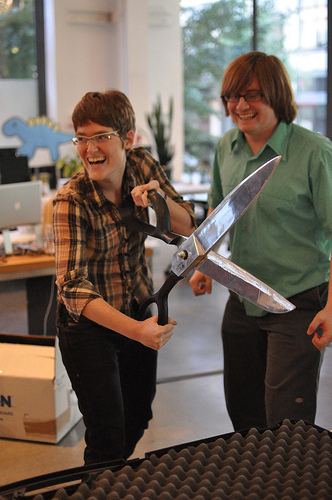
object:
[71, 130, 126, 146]
spectacles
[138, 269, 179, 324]
handle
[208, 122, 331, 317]
man shirt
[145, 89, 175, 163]
plant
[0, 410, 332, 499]
table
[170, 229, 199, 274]
dinosaur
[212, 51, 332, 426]
woman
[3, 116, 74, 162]
artwork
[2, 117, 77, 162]
dinosaur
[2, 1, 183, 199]
wall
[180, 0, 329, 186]
window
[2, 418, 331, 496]
case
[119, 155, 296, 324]
scissors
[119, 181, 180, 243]
handle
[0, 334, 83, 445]
cardboard box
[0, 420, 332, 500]
padding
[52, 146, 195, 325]
blouse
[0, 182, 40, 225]
laptop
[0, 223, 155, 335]
desk